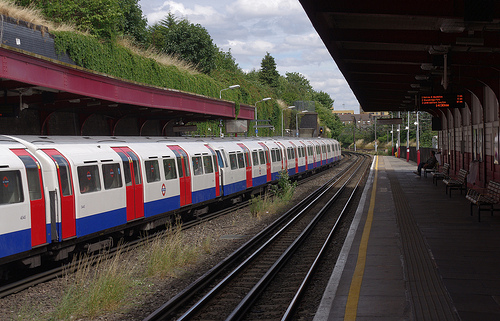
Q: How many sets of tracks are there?
A: Two.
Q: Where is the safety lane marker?
A: Before the curb.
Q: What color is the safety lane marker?
A: Yellow.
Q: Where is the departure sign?
A: Above the benches.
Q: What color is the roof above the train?
A: Maroon.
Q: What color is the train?
A: White blue and red.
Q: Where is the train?
A: On the tracks.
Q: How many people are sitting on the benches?
A: One.